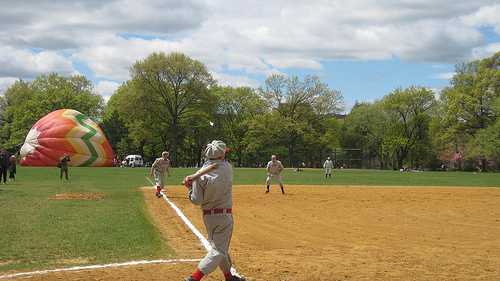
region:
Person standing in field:
[178, 118, 235, 279]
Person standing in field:
[259, 147, 284, 198]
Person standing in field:
[313, 149, 349, 194]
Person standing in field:
[141, 133, 168, 202]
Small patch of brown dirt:
[345, 260, 374, 280]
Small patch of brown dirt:
[296, 252, 329, 279]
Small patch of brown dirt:
[373, 246, 385, 267]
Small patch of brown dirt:
[392, 243, 424, 279]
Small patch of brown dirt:
[432, 239, 452, 269]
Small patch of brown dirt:
[458, 235, 478, 275]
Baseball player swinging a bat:
[162, 136, 292, 275]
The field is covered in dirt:
[299, 213, 364, 273]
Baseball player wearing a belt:
[197, 197, 244, 229]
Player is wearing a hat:
[205, 135, 227, 160]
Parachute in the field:
[3, 89, 150, 182]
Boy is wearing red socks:
[175, 246, 198, 279]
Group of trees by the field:
[125, 29, 475, 194]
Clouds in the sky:
[184, 9, 429, 89]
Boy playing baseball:
[242, 135, 307, 195]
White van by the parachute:
[117, 140, 144, 177]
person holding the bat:
[164, 136, 256, 272]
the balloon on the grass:
[21, 107, 115, 168]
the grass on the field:
[11, 163, 194, 270]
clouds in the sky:
[282, 12, 352, 43]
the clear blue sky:
[345, 64, 399, 76]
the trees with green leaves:
[132, 80, 434, 155]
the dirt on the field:
[246, 195, 498, 277]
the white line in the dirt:
[160, 193, 209, 253]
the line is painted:
[163, 198, 199, 236]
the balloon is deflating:
[18, 123, 128, 161]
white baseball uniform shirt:
[187, 155, 234, 206]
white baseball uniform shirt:
[153, 157, 169, 169]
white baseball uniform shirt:
[264, 161, 283, 171]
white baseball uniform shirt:
[321, 160, 335, 168]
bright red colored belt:
[199, 205, 235, 215]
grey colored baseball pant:
[198, 212, 231, 274]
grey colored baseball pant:
[151, 165, 166, 187]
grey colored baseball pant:
[264, 173, 283, 187]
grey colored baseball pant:
[324, 167, 331, 174]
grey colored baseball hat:
[205, 136, 230, 156]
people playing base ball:
[131, 116, 319, 264]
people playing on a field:
[102, 111, 342, 279]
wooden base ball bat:
[180, 162, 214, 186]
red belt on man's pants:
[204, 203, 237, 222]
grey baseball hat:
[202, 137, 226, 159]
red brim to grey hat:
[220, 143, 234, 153]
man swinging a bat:
[149, 128, 256, 280]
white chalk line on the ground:
[166, 193, 200, 223]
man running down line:
[140, 145, 180, 205]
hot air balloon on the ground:
[12, 102, 106, 172]